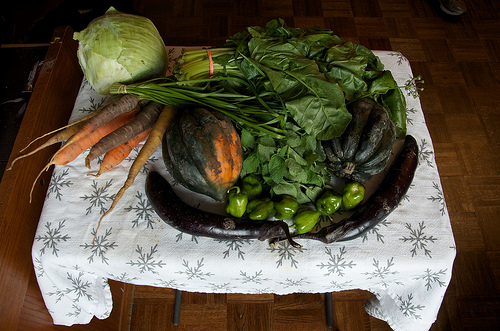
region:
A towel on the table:
[33, 53, 458, 326]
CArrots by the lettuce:
[24, 84, 172, 201]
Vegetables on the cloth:
[18, 20, 416, 245]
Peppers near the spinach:
[228, 177, 364, 232]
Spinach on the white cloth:
[239, 123, 323, 192]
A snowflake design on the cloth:
[37, 220, 117, 265]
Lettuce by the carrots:
[78, 14, 162, 91]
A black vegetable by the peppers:
[146, 170, 286, 240]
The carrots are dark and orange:
[10, 96, 176, 203]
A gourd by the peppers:
[162, 108, 242, 193]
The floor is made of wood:
[439, 51, 485, 212]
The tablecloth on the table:
[44, 209, 92, 265]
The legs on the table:
[166, 290, 338, 327]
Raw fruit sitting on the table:
[65, 4, 424, 226]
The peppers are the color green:
[223, 170, 367, 235]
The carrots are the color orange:
[46, 92, 178, 212]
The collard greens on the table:
[163, 18, 408, 114]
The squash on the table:
[164, 108, 253, 194]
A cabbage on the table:
[70, 3, 186, 95]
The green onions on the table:
[111, 64, 278, 129]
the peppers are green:
[218, 192, 284, 231]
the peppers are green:
[290, 190, 364, 227]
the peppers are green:
[291, 150, 366, 238]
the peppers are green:
[228, 200, 300, 239]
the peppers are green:
[263, 184, 353, 256]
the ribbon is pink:
[195, 35, 228, 85]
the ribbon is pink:
[196, 50, 219, 85]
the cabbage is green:
[72, 1, 182, 108]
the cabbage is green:
[40, 12, 132, 111]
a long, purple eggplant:
[137, 172, 292, 249]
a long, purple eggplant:
[323, 142, 455, 265]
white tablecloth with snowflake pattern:
[30, 40, 460, 322]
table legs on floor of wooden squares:
[10, 6, 492, 321]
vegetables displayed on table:
[6, 10, 416, 241]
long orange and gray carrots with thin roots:
[6, 100, 162, 215]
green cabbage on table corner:
[70, 6, 162, 91]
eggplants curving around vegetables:
[135, 130, 420, 250]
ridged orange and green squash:
[161, 105, 241, 200]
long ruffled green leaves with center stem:
[240, 20, 405, 135]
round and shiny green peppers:
[225, 177, 365, 229]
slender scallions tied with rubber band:
[106, 70, 286, 135]